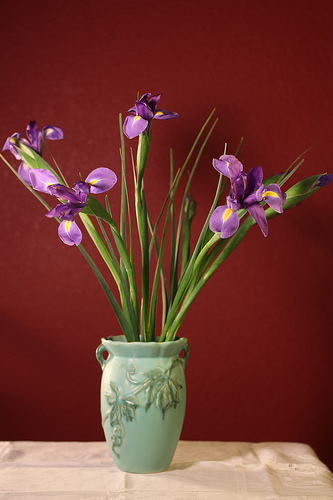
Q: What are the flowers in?
A: A vase.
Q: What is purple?
A: The flowers.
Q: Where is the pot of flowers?
A: On the table.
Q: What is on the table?
A: The vase.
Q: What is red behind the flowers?
A: The wall.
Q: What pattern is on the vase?
A: Vines.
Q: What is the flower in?
A: A vase.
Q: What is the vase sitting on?
A: Table.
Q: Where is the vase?
A: The table.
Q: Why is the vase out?
A: Display the flowers.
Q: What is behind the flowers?
A: Wall.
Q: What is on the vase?
A: Leaves.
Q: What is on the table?
A: Tablecloth.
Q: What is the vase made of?
A: Porcelain.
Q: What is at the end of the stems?
A: Flowers.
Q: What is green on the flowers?
A: Stems.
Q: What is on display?
A: Vase of flowers.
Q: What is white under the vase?
A: Tablecloth.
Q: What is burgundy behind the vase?
A: Wall.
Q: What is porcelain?
A: Vase.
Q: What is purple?
A: Flowers.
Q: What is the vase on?
A: Table.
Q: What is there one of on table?
A: Vase.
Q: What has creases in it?
A: Tablecloth.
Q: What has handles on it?
A: Vase.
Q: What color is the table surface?
A: White.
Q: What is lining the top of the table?
A: A tablecloth.